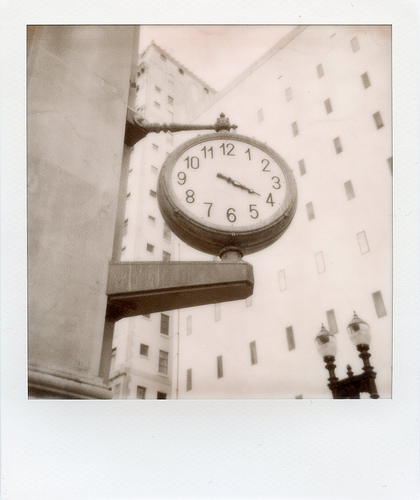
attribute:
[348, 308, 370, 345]
lamp — clear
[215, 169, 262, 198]
hand — long, black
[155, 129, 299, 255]
clock — showing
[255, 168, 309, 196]
number — black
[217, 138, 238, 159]
number — black, 12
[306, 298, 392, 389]
lamp — double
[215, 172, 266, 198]
hands — black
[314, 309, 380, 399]
lamp — higher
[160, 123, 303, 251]
clock — round, brown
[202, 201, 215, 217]
number — black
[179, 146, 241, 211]
face — white